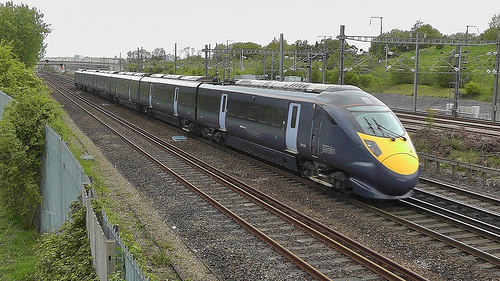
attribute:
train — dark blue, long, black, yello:
[76, 66, 419, 203]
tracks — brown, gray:
[40, 66, 499, 280]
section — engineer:
[283, 86, 417, 200]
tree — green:
[2, 2, 47, 77]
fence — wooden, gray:
[1, 87, 152, 279]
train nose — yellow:
[346, 113, 421, 193]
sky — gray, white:
[3, 1, 496, 69]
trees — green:
[0, 0, 59, 110]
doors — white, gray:
[126, 80, 305, 155]